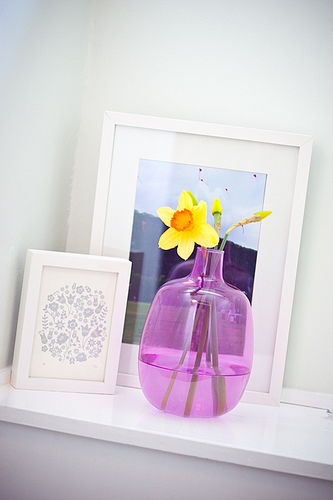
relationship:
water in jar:
[136, 354, 249, 418] [137, 246, 253, 418]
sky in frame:
[137, 156, 270, 255] [149, 163, 312, 298]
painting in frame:
[130, 153, 282, 295] [100, 111, 257, 333]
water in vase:
[136, 354, 249, 418] [137, 247, 259, 416]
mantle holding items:
[0, 365, 332, 481] [27, 218, 263, 414]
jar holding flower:
[137, 247, 253, 418] [148, 186, 221, 260]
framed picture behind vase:
[88, 111, 314, 408] [137, 247, 259, 416]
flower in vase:
[152, 191, 220, 260] [137, 247, 259, 416]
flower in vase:
[212, 197, 223, 223] [137, 247, 259, 416]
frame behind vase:
[86, 109, 314, 407] [137, 247, 259, 416]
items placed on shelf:
[8, 246, 134, 396] [0, 363, 333, 498]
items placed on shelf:
[88, 108, 314, 406] [0, 363, 333, 498]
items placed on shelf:
[136, 188, 274, 418] [0, 363, 333, 498]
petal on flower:
[155, 225, 178, 252] [152, 191, 220, 260]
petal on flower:
[154, 203, 178, 230] [152, 191, 220, 260]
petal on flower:
[174, 187, 196, 209] [152, 191, 220, 260]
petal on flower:
[192, 197, 213, 222] [152, 191, 220, 260]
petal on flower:
[193, 221, 221, 250] [152, 191, 220, 260]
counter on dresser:
[1, 359, 331, 483] [1, 357, 331, 498]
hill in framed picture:
[136, 211, 257, 303] [88, 111, 314, 408]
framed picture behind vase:
[88, 111, 314, 408] [119, 236, 271, 424]